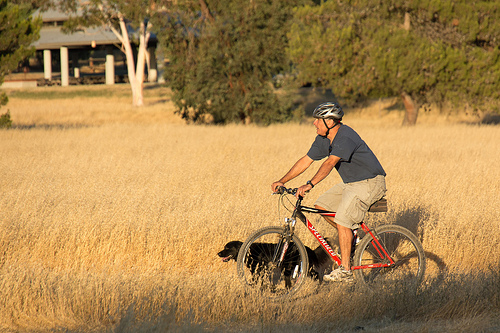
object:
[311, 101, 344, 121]
helmet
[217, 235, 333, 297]
dog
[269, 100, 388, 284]
man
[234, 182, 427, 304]
bike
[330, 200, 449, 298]
shadow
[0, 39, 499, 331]
grass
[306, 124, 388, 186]
shirt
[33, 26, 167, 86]
pavilion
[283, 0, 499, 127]
tree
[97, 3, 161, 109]
trunk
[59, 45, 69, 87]
support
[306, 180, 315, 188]
watch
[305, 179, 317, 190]
wrist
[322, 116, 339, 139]
strap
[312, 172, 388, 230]
shorts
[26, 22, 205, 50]
roof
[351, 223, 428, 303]
wheel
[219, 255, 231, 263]
tongue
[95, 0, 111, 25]
branch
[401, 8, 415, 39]
branch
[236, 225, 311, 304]
front tire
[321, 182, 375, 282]
left leg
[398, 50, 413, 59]
leaf